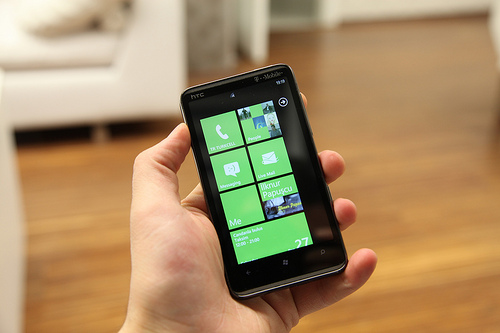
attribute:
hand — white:
[117, 91, 379, 332]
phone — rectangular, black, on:
[180, 63, 348, 300]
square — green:
[200, 111, 244, 155]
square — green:
[208, 146, 257, 192]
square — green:
[247, 137, 294, 182]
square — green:
[237, 100, 283, 143]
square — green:
[220, 183, 267, 232]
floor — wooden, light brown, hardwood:
[14, 15, 500, 333]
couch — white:
[6, 0, 188, 141]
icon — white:
[222, 162, 242, 178]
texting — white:
[220, 182, 241, 189]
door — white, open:
[271, 1, 339, 32]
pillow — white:
[0, 31, 115, 67]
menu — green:
[198, 102, 314, 265]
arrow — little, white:
[277, 96, 289, 108]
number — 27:
[293, 235, 310, 249]